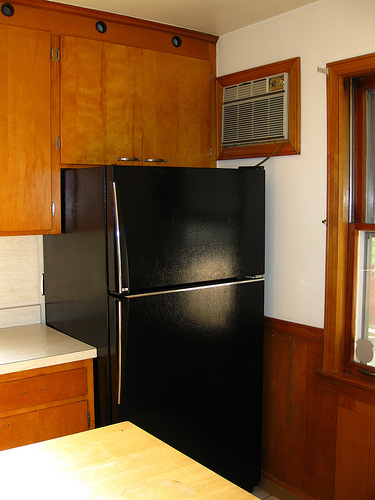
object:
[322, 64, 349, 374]
windowsill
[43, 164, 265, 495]
fridge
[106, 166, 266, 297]
freezer door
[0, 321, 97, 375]
counter top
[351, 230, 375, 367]
window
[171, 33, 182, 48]
black light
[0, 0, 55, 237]
cabinet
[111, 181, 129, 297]
handle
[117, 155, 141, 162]
chrome handle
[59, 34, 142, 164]
cabinet door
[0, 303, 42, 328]
backsplash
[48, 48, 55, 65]
hinge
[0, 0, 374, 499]
kitchen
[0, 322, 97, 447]
counter